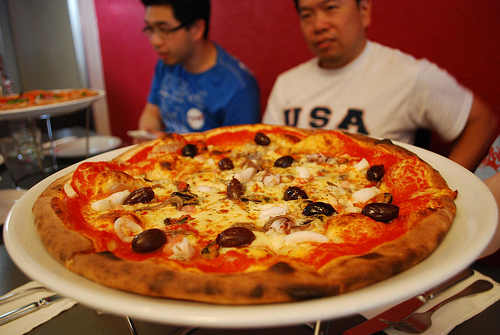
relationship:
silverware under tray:
[337, 267, 497, 334] [2, 123, 493, 329]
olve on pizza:
[282, 186, 310, 199] [33, 124, 459, 305]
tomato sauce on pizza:
[314, 225, 404, 266] [33, 124, 459, 305]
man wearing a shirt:
[254, 1, 497, 176] [261, 38, 479, 150]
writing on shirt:
[281, 105, 370, 135] [261, 38, 479, 150]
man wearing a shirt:
[130, 2, 263, 134] [143, 42, 262, 131]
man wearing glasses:
[130, 2, 263, 134] [139, 22, 195, 39]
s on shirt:
[306, 103, 332, 130] [261, 38, 479, 150]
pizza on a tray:
[33, 124, 459, 305] [2, 123, 493, 329]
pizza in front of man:
[33, 124, 459, 305] [254, 1, 497, 176]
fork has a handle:
[394, 276, 493, 334] [430, 276, 495, 310]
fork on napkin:
[394, 276, 493, 334] [358, 270, 500, 335]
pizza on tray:
[33, 124, 459, 305] [2, 123, 493, 329]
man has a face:
[254, 1, 497, 176] [297, 2, 360, 57]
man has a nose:
[254, 1, 497, 176] [311, 13, 330, 34]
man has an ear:
[254, 1, 497, 176] [357, 2, 374, 29]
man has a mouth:
[254, 1, 497, 176] [313, 35, 337, 50]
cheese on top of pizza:
[79, 133, 401, 267] [33, 124, 459, 305]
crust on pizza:
[74, 212, 459, 305] [33, 124, 459, 305]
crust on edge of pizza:
[74, 212, 459, 305] [33, 124, 459, 305]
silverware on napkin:
[337, 267, 497, 334] [358, 270, 500, 335]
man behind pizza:
[254, 1, 497, 176] [33, 124, 459, 305]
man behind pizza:
[130, 2, 263, 134] [1, 83, 104, 119]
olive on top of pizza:
[275, 154, 297, 167] [33, 124, 459, 305]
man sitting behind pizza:
[254, 1, 497, 176] [33, 124, 459, 305]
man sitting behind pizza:
[130, 2, 263, 134] [1, 83, 104, 119]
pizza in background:
[1, 83, 104, 119] [8, 3, 136, 139]